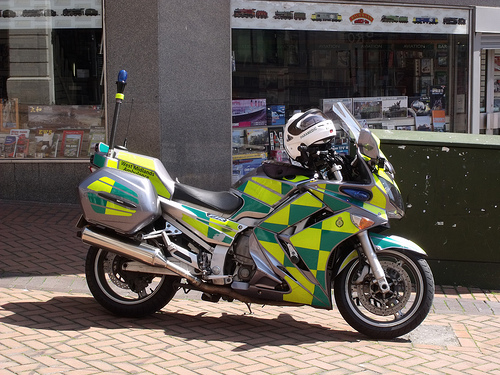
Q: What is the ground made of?
A: Brick.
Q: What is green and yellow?
A: Motorcycle.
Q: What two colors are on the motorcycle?
A: Yellow and green.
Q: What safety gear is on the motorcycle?
A: Helmet.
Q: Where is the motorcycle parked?
A: Sidewalk.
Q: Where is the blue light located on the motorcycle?
A: Back.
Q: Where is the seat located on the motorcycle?
A: Middle.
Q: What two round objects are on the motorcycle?
A: Tires.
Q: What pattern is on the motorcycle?
A: Checkered.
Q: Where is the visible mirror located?
A: Right.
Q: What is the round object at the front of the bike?
A: Wheel.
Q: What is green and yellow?
A: Motorcycle.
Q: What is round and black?
A: Tires.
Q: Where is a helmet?
A: On the bike.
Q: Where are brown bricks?
A: On the ground.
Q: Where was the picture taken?
A: A city.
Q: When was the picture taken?
A: Daytime.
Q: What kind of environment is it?
A: Urban.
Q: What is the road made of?
A: Brick.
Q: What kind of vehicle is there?
A: A motorcycle.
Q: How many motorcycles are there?
A: One.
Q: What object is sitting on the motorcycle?
A: A helmet.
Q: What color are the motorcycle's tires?
A: Black.